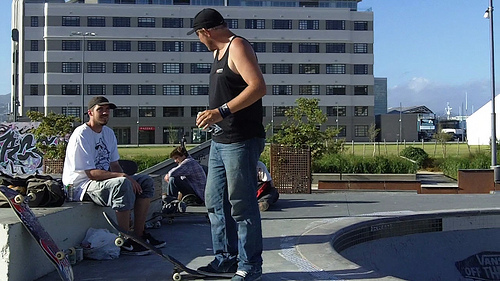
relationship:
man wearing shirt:
[66, 96, 166, 251] [60, 125, 125, 188]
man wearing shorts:
[66, 96, 166, 251] [80, 177, 156, 208]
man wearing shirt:
[185, 8, 276, 280] [205, 36, 270, 141]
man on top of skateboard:
[185, 8, 276, 280] [101, 214, 205, 280]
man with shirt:
[163, 148, 209, 204] [168, 161, 209, 197]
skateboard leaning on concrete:
[0, 183, 78, 279] [0, 195, 115, 277]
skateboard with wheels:
[0, 183, 78, 279] [16, 192, 75, 257]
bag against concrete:
[82, 226, 122, 260] [0, 195, 115, 277]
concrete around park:
[28, 161, 494, 274] [329, 206, 497, 279]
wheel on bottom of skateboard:
[115, 236, 124, 247] [101, 214, 205, 280]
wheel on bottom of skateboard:
[171, 270, 182, 280] [101, 214, 205, 280]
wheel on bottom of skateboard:
[14, 194, 25, 204] [0, 183, 78, 279]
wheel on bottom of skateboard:
[56, 249, 64, 258] [0, 183, 78, 279]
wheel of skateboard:
[115, 236, 124, 247] [101, 214, 205, 280]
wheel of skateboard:
[171, 270, 182, 280] [101, 214, 205, 280]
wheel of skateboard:
[14, 194, 25, 204] [0, 183, 78, 279]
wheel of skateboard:
[56, 249, 64, 258] [0, 183, 78, 279]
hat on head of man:
[185, 12, 229, 34] [185, 8, 276, 280]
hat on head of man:
[89, 95, 116, 109] [66, 96, 166, 251]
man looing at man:
[185, 8, 276, 280] [66, 96, 166, 251]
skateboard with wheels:
[101, 214, 205, 280] [112, 236, 181, 281]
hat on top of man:
[185, 12, 229, 34] [185, 8, 276, 280]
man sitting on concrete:
[66, 96, 166, 251] [0, 195, 115, 277]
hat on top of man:
[89, 95, 116, 109] [66, 96, 166, 251]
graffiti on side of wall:
[2, 127, 54, 170] [2, 121, 70, 173]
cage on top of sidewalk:
[271, 143, 313, 194] [249, 181, 496, 207]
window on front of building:
[62, 16, 80, 26] [14, 4, 376, 144]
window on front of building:
[87, 16, 106, 27] [14, 4, 376, 144]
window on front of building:
[112, 17, 132, 28] [14, 4, 376, 144]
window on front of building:
[139, 15, 157, 27] [14, 4, 376, 144]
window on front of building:
[162, 16, 183, 28] [14, 4, 376, 144]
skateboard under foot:
[101, 214, 205, 280] [197, 262, 241, 277]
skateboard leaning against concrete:
[0, 183, 78, 279] [0, 195, 115, 277]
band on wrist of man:
[219, 104, 233, 119] [185, 8, 276, 280]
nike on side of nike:
[121, 243, 136, 252] [117, 243, 153, 256]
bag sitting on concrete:
[82, 226, 122, 260] [0, 184, 500, 281]